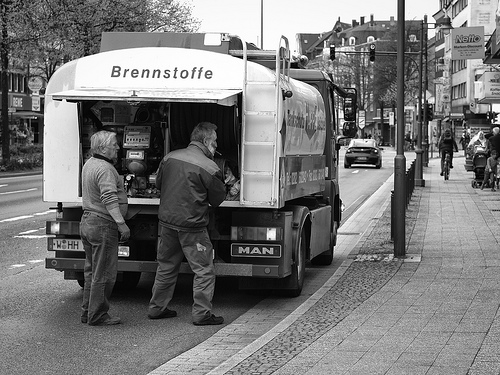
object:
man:
[145, 122, 236, 326]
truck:
[43, 41, 345, 300]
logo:
[109, 63, 214, 81]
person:
[439, 127, 459, 175]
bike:
[440, 148, 459, 180]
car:
[343, 138, 383, 168]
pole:
[393, 1, 407, 255]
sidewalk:
[204, 147, 499, 373]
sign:
[450, 26, 484, 60]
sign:
[230, 243, 281, 258]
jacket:
[153, 142, 226, 229]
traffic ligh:
[369, 43, 376, 61]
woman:
[467, 131, 493, 156]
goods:
[80, 100, 238, 199]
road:
[0, 144, 397, 374]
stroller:
[470, 151, 490, 188]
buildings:
[293, 13, 425, 141]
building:
[483, 6, 500, 74]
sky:
[146, 0, 446, 59]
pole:
[413, 19, 425, 187]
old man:
[75, 129, 131, 325]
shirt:
[77, 157, 128, 222]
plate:
[50, 239, 83, 251]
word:
[237, 246, 274, 255]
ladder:
[239, 35, 286, 204]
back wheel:
[276, 228, 306, 299]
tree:
[3, 1, 103, 82]